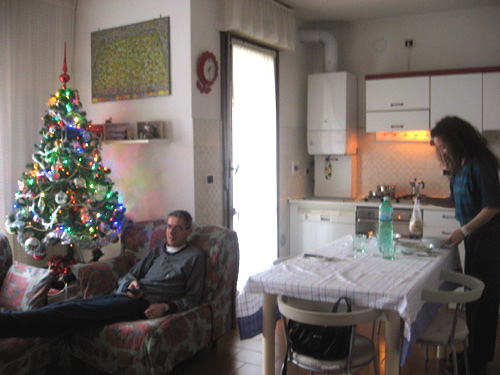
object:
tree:
[0, 66, 130, 282]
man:
[112, 199, 212, 305]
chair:
[56, 221, 260, 366]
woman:
[411, 112, 500, 343]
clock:
[189, 49, 229, 96]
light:
[377, 120, 446, 170]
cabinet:
[350, 42, 481, 142]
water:
[352, 188, 400, 275]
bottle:
[369, 185, 402, 265]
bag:
[43, 253, 75, 301]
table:
[247, 222, 468, 344]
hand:
[434, 213, 479, 264]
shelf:
[100, 108, 168, 162]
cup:
[384, 203, 437, 256]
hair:
[437, 144, 477, 188]